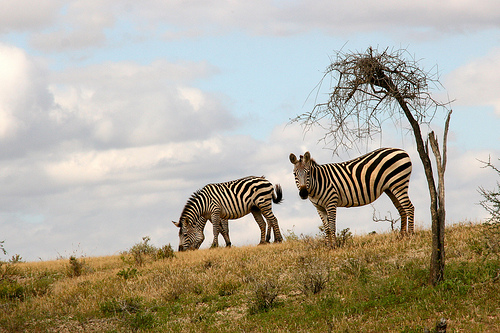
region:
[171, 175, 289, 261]
giraffes eating brown grass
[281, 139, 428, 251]
a giraffe looking at the camera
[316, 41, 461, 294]
a small tree without leaves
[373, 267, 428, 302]
a green grass under a small tree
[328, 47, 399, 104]
branches of a tree without leaves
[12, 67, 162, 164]
group of white clouds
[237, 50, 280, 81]
blue sky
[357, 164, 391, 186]
a black and white patter of the zebra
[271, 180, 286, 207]
a part of the tail of the zebra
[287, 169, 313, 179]
the eyes of the zebra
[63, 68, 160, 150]
the clouds is thick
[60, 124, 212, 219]
the clouds is thick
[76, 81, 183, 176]
the clouds is thick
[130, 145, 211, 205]
the clouds is thick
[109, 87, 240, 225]
the clouds is thick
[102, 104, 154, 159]
the clouds is thick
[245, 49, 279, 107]
this is the sky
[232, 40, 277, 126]
the sky is blue in color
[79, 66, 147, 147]
the sky has some clouds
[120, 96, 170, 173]
the clouds are white in color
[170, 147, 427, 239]
these are some zebras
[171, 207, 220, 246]
the zebras are feeding on grass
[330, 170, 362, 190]
the fur is black and white in color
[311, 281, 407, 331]
this is the grass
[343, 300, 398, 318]
the grass is green in color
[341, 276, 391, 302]
the grass is short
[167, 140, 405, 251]
A trio of zebras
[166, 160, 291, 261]
a pair of zebras eating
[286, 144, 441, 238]
a zebra looking toward the camera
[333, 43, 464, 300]
a small, dead tree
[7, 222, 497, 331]
a grassy hill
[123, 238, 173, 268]
small shrubs among the grass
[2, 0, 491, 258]
a blue, cloudy sky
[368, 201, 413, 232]
A small leafless branch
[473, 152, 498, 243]
the branches of a small bush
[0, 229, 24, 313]
the branches of a small bush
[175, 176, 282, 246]
zebra bent down eating grass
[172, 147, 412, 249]
two zebras on a hill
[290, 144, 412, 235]
zebra looking straight at the camera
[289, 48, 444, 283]
small dead tree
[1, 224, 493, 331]
brown and green grass on a hill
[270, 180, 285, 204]
zebra's tail pointing up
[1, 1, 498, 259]
mostly cloudy, gray sky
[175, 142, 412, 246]
two zebras in a natural habitat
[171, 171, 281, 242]
zebra on the left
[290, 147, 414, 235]
zebra on the right